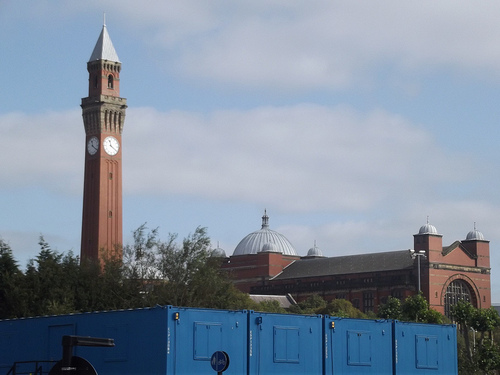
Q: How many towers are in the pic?
A: 1.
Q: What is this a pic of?
A: A clock tower.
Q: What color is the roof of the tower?
A: White.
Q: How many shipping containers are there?
A: 4.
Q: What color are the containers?
A: Blue.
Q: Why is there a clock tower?
A: So the public knows the time.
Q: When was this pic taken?
A: During the daytime.